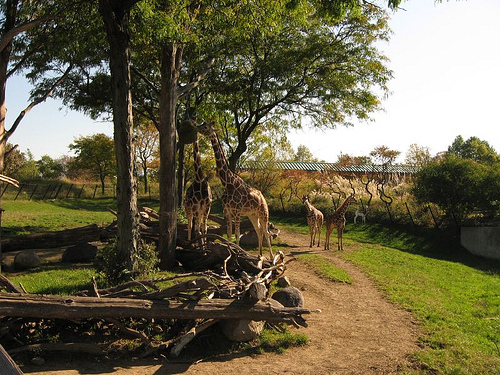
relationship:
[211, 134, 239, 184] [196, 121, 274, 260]
neck of body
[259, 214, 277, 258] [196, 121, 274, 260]
leg of body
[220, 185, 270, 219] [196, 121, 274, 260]
body of body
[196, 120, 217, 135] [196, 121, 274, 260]
head of body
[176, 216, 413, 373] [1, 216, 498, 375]
path on ground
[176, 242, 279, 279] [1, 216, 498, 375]
log on ground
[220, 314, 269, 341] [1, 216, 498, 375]
rock on ground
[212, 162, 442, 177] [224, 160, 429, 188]
roof on building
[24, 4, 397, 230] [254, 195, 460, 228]
tree by fence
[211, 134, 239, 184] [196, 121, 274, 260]
neck on body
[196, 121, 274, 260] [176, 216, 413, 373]
body by path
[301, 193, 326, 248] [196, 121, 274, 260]
baby by body